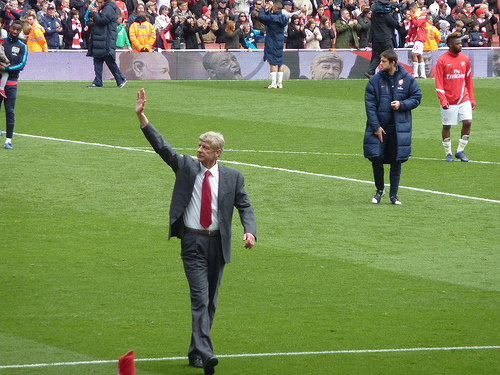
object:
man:
[135, 88, 256, 373]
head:
[197, 132, 223, 162]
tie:
[200, 171, 211, 230]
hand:
[135, 89, 144, 113]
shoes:
[455, 152, 468, 162]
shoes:
[372, 189, 385, 204]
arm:
[139, 114, 180, 165]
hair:
[198, 132, 224, 148]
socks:
[442, 140, 451, 155]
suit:
[172, 156, 236, 357]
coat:
[364, 70, 419, 161]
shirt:
[436, 51, 471, 106]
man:
[436, 35, 473, 162]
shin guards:
[462, 135, 468, 140]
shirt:
[184, 162, 219, 230]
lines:
[5, 129, 496, 203]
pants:
[372, 121, 400, 196]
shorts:
[440, 100, 472, 125]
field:
[9, 77, 500, 373]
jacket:
[129, 22, 156, 52]